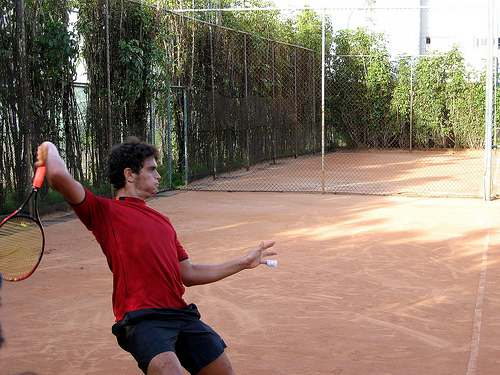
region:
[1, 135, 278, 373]
a man playing tennis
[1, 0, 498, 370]
a man playing tennis in a tennis court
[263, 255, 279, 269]
a man with a band-aid on his finger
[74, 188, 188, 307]
man wearing a red shirt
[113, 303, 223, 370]
man wearing blue shorts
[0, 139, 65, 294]
man holding a red tennis racket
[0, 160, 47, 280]
a red and black tennis racket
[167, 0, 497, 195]
a metal fence on a tennis court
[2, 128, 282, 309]
man about to swing his tennis racket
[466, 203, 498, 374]
a white line on a tennis court floor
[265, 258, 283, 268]
a white finger splint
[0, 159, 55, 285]
a red tennis racket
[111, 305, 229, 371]
a man's blue shorts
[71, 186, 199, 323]
a man's red shirt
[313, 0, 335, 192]
a long gray pole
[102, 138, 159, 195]
a man's black hair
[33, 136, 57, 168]
the hand of a man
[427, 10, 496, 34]
part of a white sky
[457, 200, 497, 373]
a long white line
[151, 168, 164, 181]
the nose of a man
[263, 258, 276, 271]
finger wrapped in white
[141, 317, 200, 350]
player is wearing blue shorts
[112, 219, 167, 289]
player's shirt is red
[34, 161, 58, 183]
handle on the racket is red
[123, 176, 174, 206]
player's cheek is puffed up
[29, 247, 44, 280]
racket is black and red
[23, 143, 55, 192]
player is swinging the racket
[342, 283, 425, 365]
court is a orange brown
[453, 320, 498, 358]
white line on the court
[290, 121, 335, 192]
fence on the court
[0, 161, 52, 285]
tennis racket is red and black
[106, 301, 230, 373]
person is wearing black shorts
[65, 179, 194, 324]
person is wearing red shirt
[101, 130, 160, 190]
person has black curly hair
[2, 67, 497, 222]
chainlink fence surrounds tennis courts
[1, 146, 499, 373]
tennis court is red and white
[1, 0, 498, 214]
trees surround chainlink fence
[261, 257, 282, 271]
man has finger taped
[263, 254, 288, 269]
white bandage on mans finger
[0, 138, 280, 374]
person is playing tennis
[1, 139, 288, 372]
Masn playing tennis game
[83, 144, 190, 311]
Man wearing red t-shirt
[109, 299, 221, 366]
Man wearing black shorts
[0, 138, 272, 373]
Man holding tennis racket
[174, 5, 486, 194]
Net dividing tennis field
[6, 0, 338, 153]
Trees beside tennis court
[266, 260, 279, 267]
White bandage on ring finger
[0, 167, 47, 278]
Red colored tennis racket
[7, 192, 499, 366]
Brown colored tennis court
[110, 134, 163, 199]
Man with short thick hair